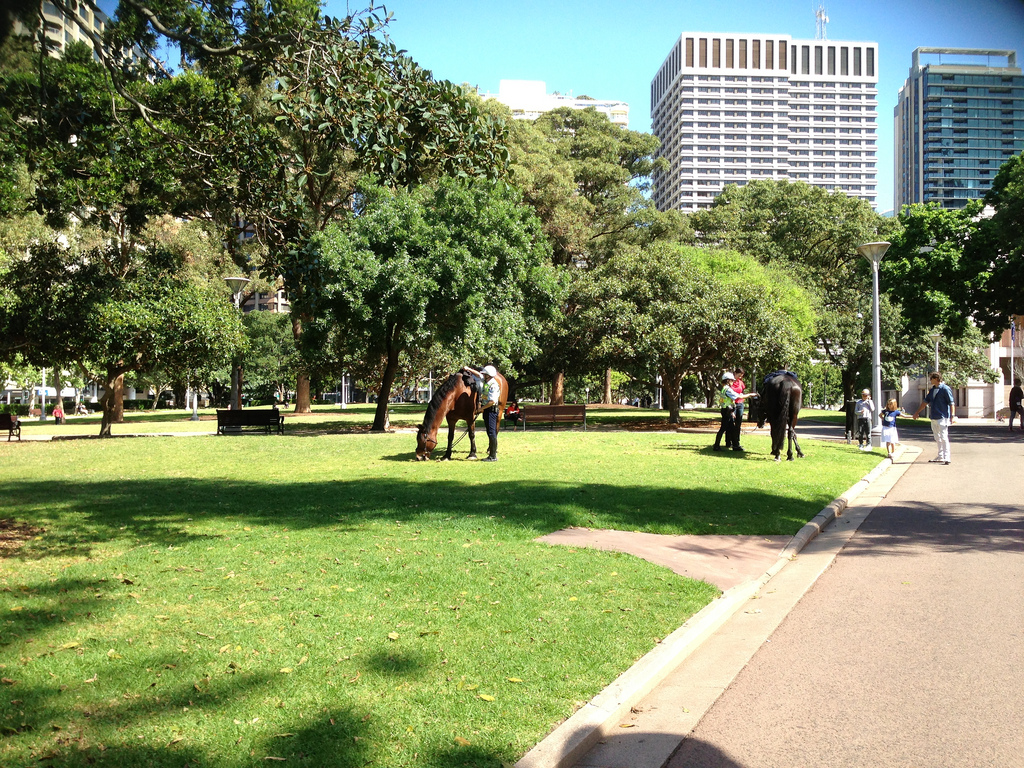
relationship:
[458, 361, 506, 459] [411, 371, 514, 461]
man with horse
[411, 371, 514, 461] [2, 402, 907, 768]
horse in park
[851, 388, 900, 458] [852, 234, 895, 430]
kids under lightpost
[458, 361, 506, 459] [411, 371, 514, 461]
man near horse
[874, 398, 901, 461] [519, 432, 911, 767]
child on curb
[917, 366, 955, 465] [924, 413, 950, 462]
man has pants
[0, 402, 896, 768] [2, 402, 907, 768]
grass in park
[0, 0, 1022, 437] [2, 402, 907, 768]
trees in park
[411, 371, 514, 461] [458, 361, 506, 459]
horse with man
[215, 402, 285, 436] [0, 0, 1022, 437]
bench under trees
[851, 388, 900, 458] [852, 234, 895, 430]
kids before lightpost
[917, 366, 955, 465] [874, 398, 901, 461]
man with child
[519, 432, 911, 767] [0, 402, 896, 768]
curb separates grass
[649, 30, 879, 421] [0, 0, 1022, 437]
building behind trees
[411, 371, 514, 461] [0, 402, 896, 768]
horse eats grass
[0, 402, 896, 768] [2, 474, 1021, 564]
grass has shadows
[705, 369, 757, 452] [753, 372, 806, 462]
people near horse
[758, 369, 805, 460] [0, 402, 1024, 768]
horse in a park